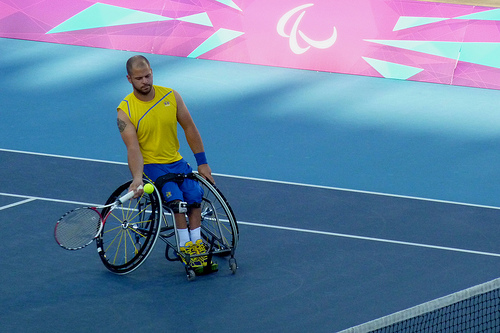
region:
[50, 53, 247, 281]
person on wheelchair playing tennis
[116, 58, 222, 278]
person in wheelchair wearing yellow shirt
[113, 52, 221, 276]
person in wheelchair wearing blue pants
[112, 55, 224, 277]
person in wheelchair wearing yellow shoes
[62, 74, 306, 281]
the man is handicapped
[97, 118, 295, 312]
the man is in a wheel chair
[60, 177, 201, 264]
the man is playing tennis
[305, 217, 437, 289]
the lines are white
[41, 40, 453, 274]
this is a tennis court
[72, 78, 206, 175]
the man has a yellow shirt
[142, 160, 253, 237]
the man has blue shorts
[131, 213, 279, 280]
the shoes are yellow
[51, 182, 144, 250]
a red white and blue tennis racket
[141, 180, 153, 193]
a yellow tennis ball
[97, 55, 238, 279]
a man in a wheelchair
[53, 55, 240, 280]
a man playing tennis in a wheelchair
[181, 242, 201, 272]
a yellow and black shoe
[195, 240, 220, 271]
a yellow and black shoe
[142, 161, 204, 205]
a pair of blue shorts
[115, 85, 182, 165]
a man's yellow sleeveless t-shirt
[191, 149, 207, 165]
a dark blue wrist band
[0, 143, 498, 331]
a blue tennis court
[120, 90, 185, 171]
the top is yellow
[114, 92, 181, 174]
the top is yellow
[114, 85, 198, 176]
the top is yellow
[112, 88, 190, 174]
the top is yellow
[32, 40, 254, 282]
man is playing tennis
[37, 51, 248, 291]
man is playing tennis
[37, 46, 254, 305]
man is playing tennis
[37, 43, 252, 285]
man is playing tennis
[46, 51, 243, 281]
person in wheelchair playing tennis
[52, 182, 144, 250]
tennis racket is red, white, and blue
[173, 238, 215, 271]
yellow laces in shoes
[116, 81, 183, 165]
yellow shirt on person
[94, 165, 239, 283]
wheel chair is specially designed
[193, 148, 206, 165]
blue wristband on person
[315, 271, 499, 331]
net is white and black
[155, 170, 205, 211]
black straps on persons legs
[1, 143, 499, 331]
white and dark blue tennis court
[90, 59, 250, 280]
wheelchair tennis player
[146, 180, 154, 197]
yellow tennis ball next to man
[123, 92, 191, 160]
yellow shirt with blue stripe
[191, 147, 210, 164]
blue wristband man is wearing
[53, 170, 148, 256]
a man holding a tennis racket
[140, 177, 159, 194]
a yellow tennis ball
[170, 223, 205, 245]
a man wearing white socks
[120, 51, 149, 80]
a man with short hair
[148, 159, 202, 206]
a man wearing blue shorts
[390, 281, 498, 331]
a white and black tennis net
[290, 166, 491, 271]
white lines on a tennis court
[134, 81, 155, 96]
a man with a beard and mustache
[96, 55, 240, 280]
the man is in a wheelchair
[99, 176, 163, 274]
the wheel is large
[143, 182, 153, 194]
the ball is green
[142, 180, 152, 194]
the ball is mid air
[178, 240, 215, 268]
the shoes are yellow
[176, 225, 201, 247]
the socks are white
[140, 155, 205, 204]
the shorts are blue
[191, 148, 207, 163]
the wristband is blue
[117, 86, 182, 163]
the shirt is yellow